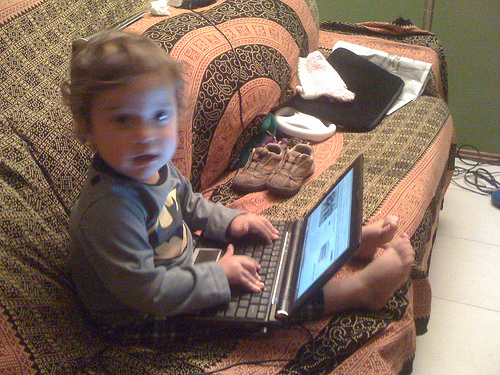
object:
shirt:
[64, 164, 242, 329]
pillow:
[329, 36, 433, 116]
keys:
[219, 247, 277, 291]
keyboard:
[180, 220, 285, 324]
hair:
[62, 30, 187, 137]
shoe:
[233, 142, 285, 191]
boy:
[64, 32, 417, 350]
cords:
[455, 147, 499, 208]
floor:
[400, 142, 500, 375]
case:
[289, 47, 403, 132]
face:
[93, 72, 185, 181]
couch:
[0, 0, 457, 374]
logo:
[141, 182, 184, 261]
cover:
[0, 0, 456, 374]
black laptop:
[290, 48, 405, 133]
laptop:
[177, 153, 363, 328]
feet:
[358, 231, 415, 311]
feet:
[353, 212, 401, 264]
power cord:
[185, 3, 247, 144]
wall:
[317, 1, 499, 161]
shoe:
[265, 141, 312, 195]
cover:
[271, 35, 437, 145]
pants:
[109, 309, 229, 342]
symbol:
[141, 179, 191, 269]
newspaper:
[334, 39, 433, 119]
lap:
[150, 317, 290, 335]